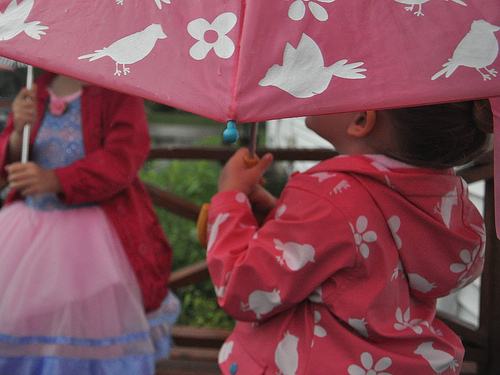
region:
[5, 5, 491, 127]
pink umbrella with white birds and flowers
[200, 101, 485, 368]
pink sweatshirt with white birds and flowers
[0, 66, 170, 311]
long red jacket over party dress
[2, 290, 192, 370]
blue ribbon on hem of pink skirt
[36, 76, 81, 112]
pink flower at neckline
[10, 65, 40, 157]
hand curled around umbrella pole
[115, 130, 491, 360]
wooden railing behind children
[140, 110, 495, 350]
grass and white building beyond railing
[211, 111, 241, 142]
blue finial on tip of umbrella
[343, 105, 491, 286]
hood hanging underneath head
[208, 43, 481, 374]
a baby under an umbrella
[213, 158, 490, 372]
a pink rain jacket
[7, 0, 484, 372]
the jacket and the umbrella are matching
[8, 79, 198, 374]
a girl wearing a dress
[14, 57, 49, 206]
the pole of an umbrella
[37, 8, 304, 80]
bird and flower pattern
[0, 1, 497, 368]
the jacket and umbrella feature a bird and flower pattern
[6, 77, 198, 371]
she is in a princess costume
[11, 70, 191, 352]
she is wearing a red jacket over her dress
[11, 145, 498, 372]
there is a wooden fence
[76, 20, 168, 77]
Small white bird painted on umbrella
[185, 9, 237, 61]
White four petaled flower painted on umbrella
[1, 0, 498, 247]
Pink and white umbrella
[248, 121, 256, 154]
Gray metal part of umbrella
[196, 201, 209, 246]
Curved wooden umbrella handle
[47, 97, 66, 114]
Pink flower decoration at top of girl's shirt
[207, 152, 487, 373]
Little girl's pink and white rain jacket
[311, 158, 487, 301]
Pink hood of little girl's rain jacket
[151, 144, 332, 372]
Dark wood stained fence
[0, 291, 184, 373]
Blue satin trim on little girl's pink skirt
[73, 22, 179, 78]
White bird umbrella decoraion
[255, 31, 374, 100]
White bird umbrella decoation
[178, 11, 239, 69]
White flower umbrella decoration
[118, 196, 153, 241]
Part of childs red jacket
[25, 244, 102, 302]
Part of child's pink dress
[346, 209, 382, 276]
White flower jacket decoration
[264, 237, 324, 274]
White bird jacket decoration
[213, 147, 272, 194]
hand of child holding umbrella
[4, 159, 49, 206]
Hand of child holding umbrella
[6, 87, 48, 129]
Hand of child holding umbrella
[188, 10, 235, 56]
white flower on the umbrella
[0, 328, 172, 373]
blue lines on the dress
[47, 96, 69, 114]
pink flower on the dress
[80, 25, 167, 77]
bird on the umbrella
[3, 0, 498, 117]
red umbrella with white pattern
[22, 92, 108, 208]
blue sparkle top on the dress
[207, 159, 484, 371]
girl's hooded jacket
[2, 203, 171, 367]
pink skirt on the dress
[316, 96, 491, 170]
little girl with brown hair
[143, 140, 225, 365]
brown wooden fence